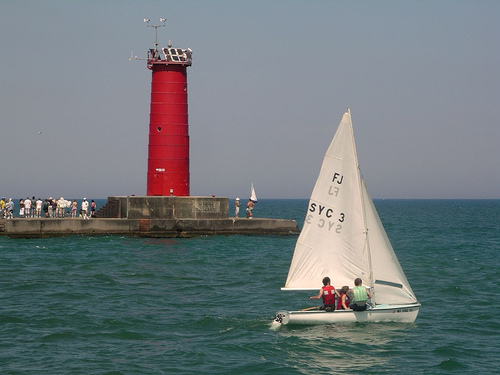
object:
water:
[1, 243, 275, 373]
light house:
[147, 49, 190, 197]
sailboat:
[270, 109, 422, 330]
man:
[311, 277, 341, 314]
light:
[142, 15, 165, 30]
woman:
[337, 284, 352, 312]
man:
[348, 277, 372, 311]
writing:
[305, 171, 345, 232]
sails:
[282, 109, 417, 305]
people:
[242, 197, 264, 222]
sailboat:
[250, 181, 259, 203]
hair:
[322, 277, 331, 285]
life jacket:
[322, 284, 336, 306]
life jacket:
[355, 286, 366, 303]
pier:
[1, 197, 300, 237]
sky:
[0, 0, 499, 113]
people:
[77, 196, 94, 219]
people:
[233, 197, 246, 220]